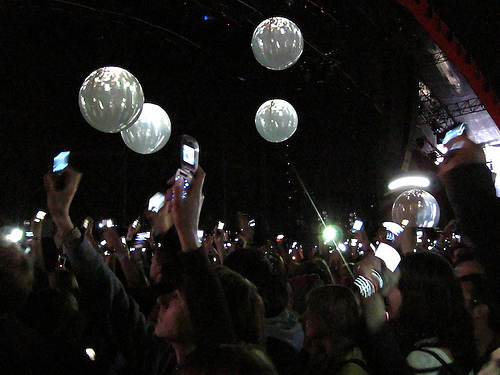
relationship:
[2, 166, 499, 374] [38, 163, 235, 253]
people have arms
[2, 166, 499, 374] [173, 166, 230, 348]
people has arm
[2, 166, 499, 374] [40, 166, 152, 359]
people has arm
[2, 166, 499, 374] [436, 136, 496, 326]
people has arm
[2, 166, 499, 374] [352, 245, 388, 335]
people has arm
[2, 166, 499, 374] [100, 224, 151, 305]
people has arm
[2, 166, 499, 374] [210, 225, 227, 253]
people has hand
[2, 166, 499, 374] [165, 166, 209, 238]
people has hand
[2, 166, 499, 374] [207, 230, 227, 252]
people has hand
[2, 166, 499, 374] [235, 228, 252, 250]
people has hand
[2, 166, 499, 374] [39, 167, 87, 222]
people has hand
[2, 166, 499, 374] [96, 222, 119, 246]
people has hand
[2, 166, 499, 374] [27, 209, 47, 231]
people has hand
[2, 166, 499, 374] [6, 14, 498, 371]
people in warehouse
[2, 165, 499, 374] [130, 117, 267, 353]
people holding phones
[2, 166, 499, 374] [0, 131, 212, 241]
people holding phones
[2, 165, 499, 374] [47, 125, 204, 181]
people holding phones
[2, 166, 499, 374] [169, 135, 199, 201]
people holding cellular phone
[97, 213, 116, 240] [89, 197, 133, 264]
cellphone held hand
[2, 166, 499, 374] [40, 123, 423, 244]
people holding cellphones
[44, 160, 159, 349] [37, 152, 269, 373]
arm of person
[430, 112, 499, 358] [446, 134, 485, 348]
arm of person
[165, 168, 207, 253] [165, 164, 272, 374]
hand of person